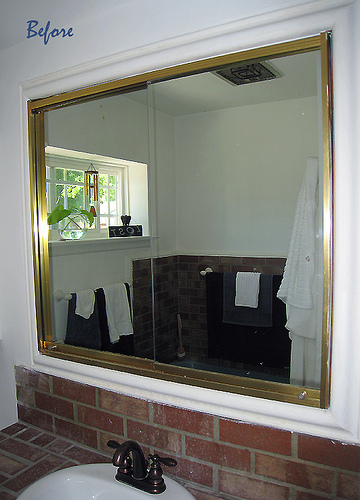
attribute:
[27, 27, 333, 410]
mirror — big, large, brass trimmed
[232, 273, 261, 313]
towel — white, hanging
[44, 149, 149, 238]
window — white, of window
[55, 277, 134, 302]
rack — white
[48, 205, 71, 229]
leaf — large, green, bright green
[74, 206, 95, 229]
leaf — large, green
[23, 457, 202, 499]
sink — white, porcelain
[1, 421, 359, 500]
counter — brick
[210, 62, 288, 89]
extractor fan — black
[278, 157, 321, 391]
bathrobe — hanging, white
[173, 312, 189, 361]
reflection — of toilet brush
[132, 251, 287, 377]
wall — brick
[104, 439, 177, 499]
fixture — bronze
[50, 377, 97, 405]
brick — red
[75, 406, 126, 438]
brick — red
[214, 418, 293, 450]
brick — red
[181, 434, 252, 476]
brick — red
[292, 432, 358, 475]
brick — red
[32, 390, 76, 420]
brick — red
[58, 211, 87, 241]
bowl — glass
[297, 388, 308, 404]
screw — silver, metal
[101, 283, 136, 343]
towel — white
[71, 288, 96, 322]
towel — white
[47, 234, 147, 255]
edge — large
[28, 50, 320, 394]
glass — transparent